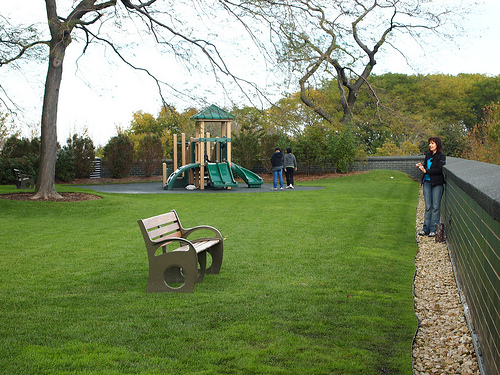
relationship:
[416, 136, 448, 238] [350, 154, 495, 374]
woman by wall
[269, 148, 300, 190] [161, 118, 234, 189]
people by gilded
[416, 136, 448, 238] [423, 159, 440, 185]
woman in blue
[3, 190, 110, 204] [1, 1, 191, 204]
gravel near tree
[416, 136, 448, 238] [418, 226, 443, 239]
woman wearing shoes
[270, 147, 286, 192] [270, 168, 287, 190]
man wearing jeans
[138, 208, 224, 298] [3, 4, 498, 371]
bench in park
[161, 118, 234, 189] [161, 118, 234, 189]
gilded play gilded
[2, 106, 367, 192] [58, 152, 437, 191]
trees near fence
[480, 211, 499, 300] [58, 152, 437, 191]
bricks in fence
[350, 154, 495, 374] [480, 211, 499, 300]
wall of bricks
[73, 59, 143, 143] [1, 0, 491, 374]
clear day outside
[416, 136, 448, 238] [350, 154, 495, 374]
woman near wall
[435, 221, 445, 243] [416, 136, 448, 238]
bag near woman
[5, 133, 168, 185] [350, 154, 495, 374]
bushes near wall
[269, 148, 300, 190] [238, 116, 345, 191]
people in area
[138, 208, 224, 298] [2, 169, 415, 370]
bench on grass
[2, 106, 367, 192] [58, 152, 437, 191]
trees behind wall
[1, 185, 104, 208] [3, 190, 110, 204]
circular grass clearing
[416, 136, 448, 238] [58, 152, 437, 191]
woman by fence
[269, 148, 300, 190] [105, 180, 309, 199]
couple on walk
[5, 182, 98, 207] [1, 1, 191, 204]
bud of tree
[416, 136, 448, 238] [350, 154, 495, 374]
lady against wall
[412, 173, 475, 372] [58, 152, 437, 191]
border by fence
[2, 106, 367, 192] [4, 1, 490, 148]
trees in background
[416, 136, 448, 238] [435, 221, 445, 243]
woman by bag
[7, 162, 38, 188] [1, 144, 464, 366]
bench at other side of park